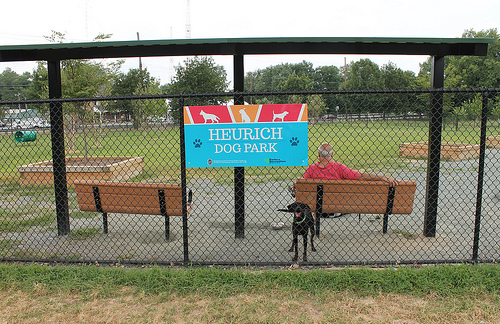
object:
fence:
[1, 87, 499, 267]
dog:
[277, 201, 319, 262]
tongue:
[296, 212, 301, 217]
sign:
[183, 123, 308, 168]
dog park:
[213, 142, 278, 153]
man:
[288, 142, 399, 195]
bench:
[290, 178, 413, 232]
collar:
[291, 216, 310, 224]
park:
[0, 116, 499, 263]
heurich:
[209, 126, 284, 141]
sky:
[0, 0, 499, 89]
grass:
[1, 263, 497, 293]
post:
[177, 97, 192, 263]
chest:
[294, 220, 306, 235]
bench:
[73, 178, 195, 239]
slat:
[77, 192, 185, 208]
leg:
[382, 213, 389, 233]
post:
[472, 94, 491, 262]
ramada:
[0, 35, 490, 241]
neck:
[320, 158, 330, 164]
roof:
[1, 34, 494, 60]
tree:
[30, 33, 109, 124]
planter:
[19, 155, 147, 188]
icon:
[290, 137, 300, 146]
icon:
[193, 139, 203, 148]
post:
[422, 56, 447, 237]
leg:
[163, 216, 171, 241]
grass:
[0, 121, 500, 169]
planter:
[395, 139, 484, 161]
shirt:
[302, 159, 360, 180]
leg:
[102, 211, 108, 234]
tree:
[167, 56, 236, 127]